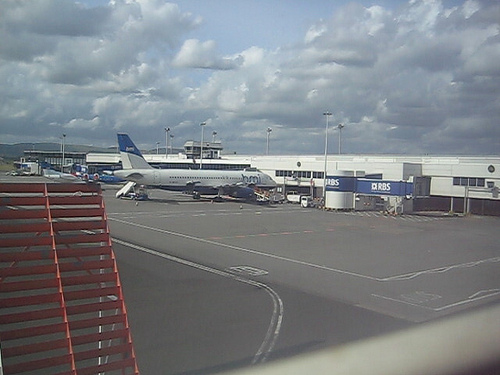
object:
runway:
[0, 172, 500, 375]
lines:
[105, 207, 500, 366]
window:
[474, 179, 484, 188]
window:
[468, 178, 476, 186]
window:
[461, 177, 468, 185]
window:
[453, 177, 460, 185]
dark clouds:
[0, 0, 500, 148]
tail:
[116, 132, 153, 170]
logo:
[325, 178, 392, 194]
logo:
[125, 146, 134, 151]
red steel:
[0, 182, 139, 375]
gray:
[302, 69, 402, 118]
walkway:
[2, 167, 491, 373]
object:
[0, 180, 141, 375]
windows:
[167, 163, 252, 170]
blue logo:
[241, 174, 261, 185]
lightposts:
[199, 121, 207, 169]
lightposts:
[322, 109, 332, 197]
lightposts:
[164, 124, 170, 158]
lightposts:
[62, 132, 67, 176]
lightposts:
[265, 127, 273, 155]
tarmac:
[1, 146, 500, 375]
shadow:
[137, 196, 255, 206]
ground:
[91, 185, 498, 372]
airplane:
[112, 131, 281, 199]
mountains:
[0, 141, 181, 172]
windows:
[169, 176, 240, 180]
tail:
[33, 183, 141, 375]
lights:
[323, 111, 333, 116]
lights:
[336, 123, 344, 129]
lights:
[265, 126, 273, 132]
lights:
[212, 130, 218, 136]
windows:
[275, 169, 326, 179]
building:
[85, 153, 500, 218]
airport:
[0, 130, 500, 375]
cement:
[8, 168, 496, 373]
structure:
[0, 181, 141, 375]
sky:
[0, 0, 500, 167]